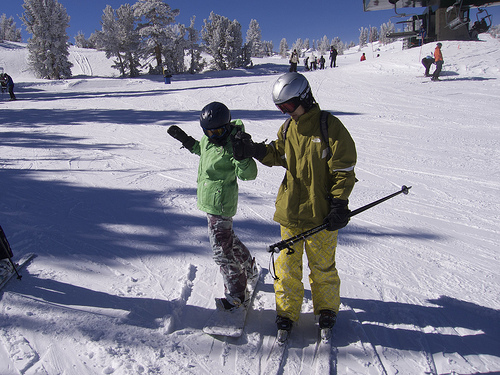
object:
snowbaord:
[202, 262, 263, 338]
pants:
[274, 220, 342, 323]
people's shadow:
[2, 265, 500, 358]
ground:
[2, 36, 499, 375]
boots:
[274, 309, 336, 342]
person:
[233, 71, 356, 347]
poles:
[268, 184, 421, 271]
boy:
[165, 101, 257, 311]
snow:
[0, 35, 499, 371]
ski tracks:
[433, 170, 483, 241]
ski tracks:
[461, 75, 486, 101]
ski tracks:
[353, 317, 434, 370]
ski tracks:
[97, 231, 138, 291]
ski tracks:
[151, 146, 179, 186]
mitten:
[167, 124, 189, 142]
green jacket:
[188, 117, 258, 218]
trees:
[242, 19, 423, 49]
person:
[432, 43, 443, 82]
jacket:
[433, 46, 447, 63]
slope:
[0, 31, 500, 373]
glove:
[323, 197, 350, 231]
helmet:
[200, 101, 232, 129]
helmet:
[272, 72, 312, 115]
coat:
[260, 103, 357, 230]